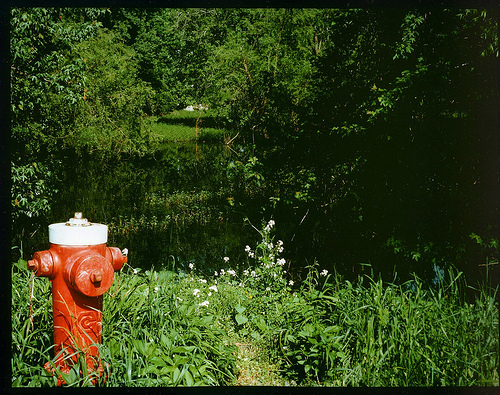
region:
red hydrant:
[20, 195, 141, 353]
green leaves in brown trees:
[145, 61, 186, 81]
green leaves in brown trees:
[342, 45, 369, 93]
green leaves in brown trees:
[402, 153, 430, 195]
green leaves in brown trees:
[288, 128, 339, 172]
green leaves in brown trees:
[407, 56, 468, 163]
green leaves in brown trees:
[224, 22, 299, 92]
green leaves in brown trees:
[25, 9, 110, 89]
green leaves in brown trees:
[42, 65, 120, 135]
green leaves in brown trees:
[104, 52, 155, 96]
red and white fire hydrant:
[31, 206, 129, 381]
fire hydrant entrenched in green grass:
[22, 211, 157, 385]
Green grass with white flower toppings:
[107, 196, 332, 348]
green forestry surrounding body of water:
[23, 90, 487, 346]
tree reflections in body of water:
[17, 121, 314, 269]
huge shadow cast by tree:
[145, 91, 254, 145]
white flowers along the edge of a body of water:
[89, 199, 459, 311]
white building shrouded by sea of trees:
[105, 11, 286, 159]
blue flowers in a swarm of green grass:
[367, 255, 488, 335]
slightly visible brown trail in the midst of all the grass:
[152, 266, 354, 388]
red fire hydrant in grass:
[18, 208, 136, 393]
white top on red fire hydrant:
[37, 203, 115, 249]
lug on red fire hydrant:
[86, 266, 110, 288]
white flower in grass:
[177, 212, 339, 312]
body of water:
[59, 188, 434, 288]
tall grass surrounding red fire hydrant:
[13, 257, 233, 392]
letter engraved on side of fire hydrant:
[72, 308, 101, 340]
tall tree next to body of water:
[8, 6, 106, 253]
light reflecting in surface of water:
[208, 220, 243, 257]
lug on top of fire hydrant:
[63, 205, 92, 227]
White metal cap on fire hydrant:
[46, 211, 108, 245]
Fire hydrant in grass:
[26, 209, 131, 385]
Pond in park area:
[16, 145, 496, 302]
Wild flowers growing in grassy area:
[136, 210, 334, 312]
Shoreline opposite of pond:
[6, 109, 257, 139]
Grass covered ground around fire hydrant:
[16, 264, 494, 385]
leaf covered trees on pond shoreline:
[11, 7, 496, 137]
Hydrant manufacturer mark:
[73, 308, 98, 333]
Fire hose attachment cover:
[68, 252, 115, 296]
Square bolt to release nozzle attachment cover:
[90, 272, 104, 284]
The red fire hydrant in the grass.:
[26, 210, 127, 390]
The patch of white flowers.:
[188, 225, 303, 305]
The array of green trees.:
[17, 13, 487, 160]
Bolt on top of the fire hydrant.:
[65, 208, 92, 229]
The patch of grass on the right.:
[332, 283, 494, 386]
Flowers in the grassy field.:
[177, 211, 457, 358]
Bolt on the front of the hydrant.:
[70, 250, 112, 296]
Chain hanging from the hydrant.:
[27, 270, 45, 332]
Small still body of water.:
[108, 161, 477, 276]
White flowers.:
[183, 94, 230, 121]